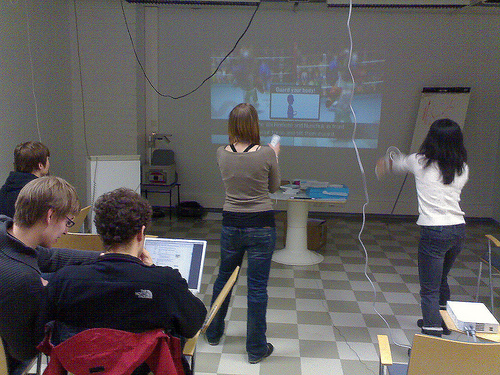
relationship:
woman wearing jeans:
[204, 92, 282, 367] [219, 227, 271, 338]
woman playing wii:
[204, 92, 282, 367] [444, 299, 498, 338]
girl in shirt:
[378, 109, 492, 274] [386, 150, 470, 225]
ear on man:
[137, 224, 147, 240] [90, 177, 196, 330]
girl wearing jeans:
[378, 109, 492, 274] [418, 222, 466, 337]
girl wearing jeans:
[203, 99, 317, 368] [202, 223, 277, 363]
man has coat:
[39, 189, 206, 334] [34, 309, 194, 374]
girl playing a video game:
[378, 109, 492, 274] [447, 296, 497, 331]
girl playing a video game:
[203, 99, 317, 368] [447, 296, 497, 331]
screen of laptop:
[143, 240, 198, 289] [142, 226, 204, 324]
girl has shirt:
[203, 99, 317, 368] [210, 139, 292, 227]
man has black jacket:
[66, 162, 198, 322] [60, 244, 212, 357]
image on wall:
[188, 50, 403, 112] [97, 7, 199, 122]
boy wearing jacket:
[41, 189, 205, 372] [57, 238, 229, 351]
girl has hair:
[203, 99, 317, 368] [227, 102, 262, 142]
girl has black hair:
[378, 109, 492, 274] [417, 115, 470, 185]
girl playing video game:
[203, 99, 317, 368] [92, 45, 496, 325]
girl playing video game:
[378, 109, 492, 274] [92, 45, 496, 325]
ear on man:
[38, 203, 63, 228] [49, 186, 223, 353]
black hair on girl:
[417, 115, 470, 185] [401, 113, 468, 295]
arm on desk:
[370, 315, 406, 372] [369, 327, 499, 369]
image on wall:
[188, 0, 399, 125] [70, 5, 497, 219]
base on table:
[265, 192, 328, 271] [260, 176, 354, 272]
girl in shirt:
[378, 109, 492, 274] [385, 110, 483, 232]